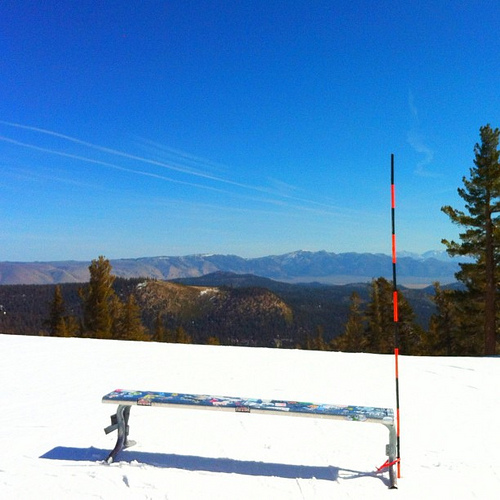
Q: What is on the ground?
A: Snow.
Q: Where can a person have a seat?
A: On the bench.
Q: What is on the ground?
A: Snow.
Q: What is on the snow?
A: A shadow.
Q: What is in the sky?
A: Wispy clouds.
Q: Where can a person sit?
A: On the bench.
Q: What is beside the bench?
A: A red and black pole.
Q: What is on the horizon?
A: Mountains.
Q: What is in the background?
A: Trees.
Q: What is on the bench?
A: Stickers.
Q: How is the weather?
A: Cold.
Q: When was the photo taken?
A: During the daytime.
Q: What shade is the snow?
A: White.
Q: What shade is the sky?
A: Blue.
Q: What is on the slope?
A: Trees.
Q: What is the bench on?
A: Snow.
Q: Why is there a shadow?
A: The bench.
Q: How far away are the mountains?
A: Far away.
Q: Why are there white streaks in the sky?
A: Planes.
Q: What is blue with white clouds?
A: The sky.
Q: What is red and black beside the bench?
A: A pole.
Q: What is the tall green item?
A: A tree.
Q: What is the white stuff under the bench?
A: Snow.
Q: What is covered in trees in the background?
A: Mountains.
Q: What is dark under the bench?
A: A shadow.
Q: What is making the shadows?
A: The bench.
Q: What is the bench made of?
A: Metal.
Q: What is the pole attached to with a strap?
A: The bench.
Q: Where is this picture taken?
A: A ski slope.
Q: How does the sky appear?
A: Blue.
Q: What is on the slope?
A: A bench.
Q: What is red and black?
A: A pole marker.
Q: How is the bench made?
A: Of skis.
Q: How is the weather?
A: Sunny and clear.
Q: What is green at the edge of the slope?
A: Trees.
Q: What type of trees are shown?
A: Evergreen.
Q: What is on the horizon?
A: Mountains.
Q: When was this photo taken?
A: Daytime.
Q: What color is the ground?
A: White.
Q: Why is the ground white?
A: Snow.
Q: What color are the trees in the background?
A: Green.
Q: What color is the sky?
A: Blue.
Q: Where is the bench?
A: In the middle of the snow.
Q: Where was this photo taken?
A: Top of hill.